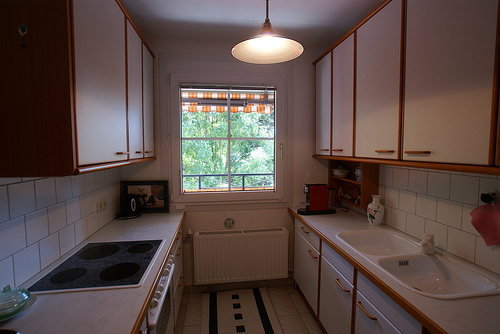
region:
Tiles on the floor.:
[267, 290, 303, 332]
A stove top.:
[22, 234, 169, 298]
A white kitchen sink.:
[358, 228, 478, 300]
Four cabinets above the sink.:
[311, 6, 486, 162]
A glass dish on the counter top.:
[0, 277, 46, 324]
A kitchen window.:
[171, 85, 284, 202]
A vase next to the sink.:
[358, 186, 388, 228]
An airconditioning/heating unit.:
[186, 212, 292, 287]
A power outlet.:
[77, 190, 113, 217]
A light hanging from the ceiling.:
[222, 2, 329, 94]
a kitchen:
[12, 5, 494, 326]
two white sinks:
[348, 225, 490, 306]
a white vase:
[360, 190, 388, 226]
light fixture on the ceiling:
[225, 0, 316, 73]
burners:
[35, 230, 155, 291]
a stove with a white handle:
[150, 270, 185, 331]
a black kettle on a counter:
[115, 192, 145, 218]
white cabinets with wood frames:
[315, 20, 496, 162]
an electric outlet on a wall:
[92, 196, 110, 216]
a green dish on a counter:
[1, 275, 36, 327]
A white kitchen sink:
[333, 220, 498, 302]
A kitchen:
[6, 23, 498, 331]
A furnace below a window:
[189, 226, 301, 288]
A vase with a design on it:
[365, 193, 388, 233]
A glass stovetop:
[25, 225, 167, 296]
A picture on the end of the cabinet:
[119, 178, 171, 213]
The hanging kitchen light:
[228, 1, 315, 87]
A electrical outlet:
[94, 195, 111, 217]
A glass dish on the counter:
[2, 278, 40, 332]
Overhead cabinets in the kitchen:
[299, 0, 499, 186]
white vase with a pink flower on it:
[365, 190, 386, 230]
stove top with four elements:
[29, 235, 169, 290]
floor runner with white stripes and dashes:
[202, 288, 277, 332]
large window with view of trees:
[170, 71, 286, 201]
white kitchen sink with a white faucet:
[337, 230, 499, 295]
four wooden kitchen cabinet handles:
[311, 143, 432, 158]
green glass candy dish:
[0, 284, 37, 319]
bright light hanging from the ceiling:
[228, 19, 306, 67]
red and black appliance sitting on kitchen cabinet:
[295, 181, 339, 215]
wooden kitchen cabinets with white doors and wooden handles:
[0, 2, 158, 172]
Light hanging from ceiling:
[210, 7, 312, 89]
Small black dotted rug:
[200, 292, 269, 332]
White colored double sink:
[346, 215, 492, 297]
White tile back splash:
[10, 192, 81, 256]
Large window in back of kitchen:
[167, 81, 288, 199]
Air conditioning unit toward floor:
[183, 215, 302, 292]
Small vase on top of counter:
[360, 194, 392, 226]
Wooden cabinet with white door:
[25, 17, 135, 174]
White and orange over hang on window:
[172, 82, 279, 112]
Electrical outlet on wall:
[93, 195, 109, 213]